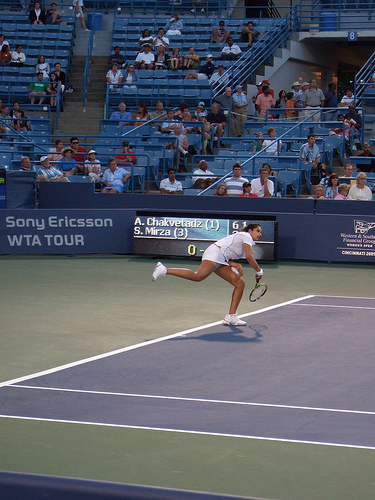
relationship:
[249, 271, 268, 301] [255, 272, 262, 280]
tennis racket in womans hand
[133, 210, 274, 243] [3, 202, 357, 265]
scoreboard against wall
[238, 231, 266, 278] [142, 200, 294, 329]
arm of woman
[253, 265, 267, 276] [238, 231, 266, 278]
wristband on arm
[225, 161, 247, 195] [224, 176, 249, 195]
man wearing shirt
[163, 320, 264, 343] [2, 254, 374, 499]
shadow on ground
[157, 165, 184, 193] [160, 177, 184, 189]
man wearing shirt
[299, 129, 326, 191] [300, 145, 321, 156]
man wearing shirt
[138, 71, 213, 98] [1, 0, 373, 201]
blue bleachers in stands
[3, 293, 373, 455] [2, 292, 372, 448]
surface of court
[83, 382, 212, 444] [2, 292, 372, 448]
lines on court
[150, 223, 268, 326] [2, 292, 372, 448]
game controller on court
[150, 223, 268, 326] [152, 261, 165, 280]
game controller wearing shoes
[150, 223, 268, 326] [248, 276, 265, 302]
game controller swinging tennis racket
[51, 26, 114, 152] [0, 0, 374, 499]
stairs in stadium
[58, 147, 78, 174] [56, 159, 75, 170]
person wearing shirt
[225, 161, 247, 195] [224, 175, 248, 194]
man in shirt